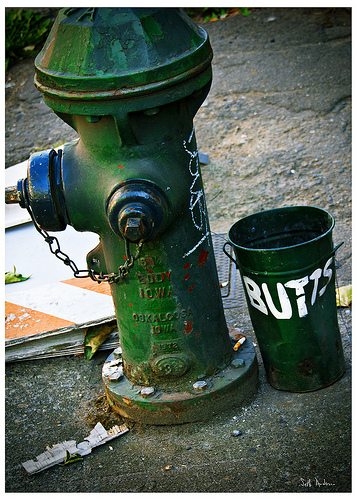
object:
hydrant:
[4, 5, 260, 425]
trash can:
[222, 204, 346, 391]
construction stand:
[5, 139, 141, 363]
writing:
[132, 273, 195, 350]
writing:
[243, 258, 334, 320]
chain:
[25, 200, 142, 285]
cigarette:
[233, 337, 245, 351]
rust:
[183, 247, 210, 336]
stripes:
[4, 274, 114, 343]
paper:
[20, 420, 131, 476]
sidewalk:
[5, 6, 352, 493]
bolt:
[123, 218, 145, 243]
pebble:
[232, 430, 241, 436]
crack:
[227, 37, 349, 53]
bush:
[5, 5, 235, 74]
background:
[5, 8, 350, 97]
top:
[32, 8, 212, 93]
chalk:
[180, 126, 211, 258]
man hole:
[210, 230, 245, 309]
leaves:
[5, 265, 30, 286]